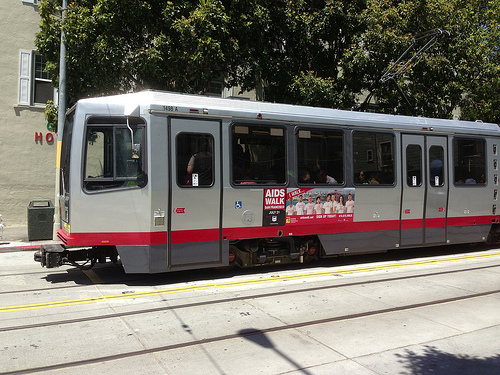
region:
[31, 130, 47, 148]
red letter on building.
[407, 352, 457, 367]
shadow on the sidewalk.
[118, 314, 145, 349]
concrete between the tracks.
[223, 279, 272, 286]
yellow paint on concrete.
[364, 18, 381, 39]
leaves on the tree.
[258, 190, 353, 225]
poster on the train.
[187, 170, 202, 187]
sign on the door.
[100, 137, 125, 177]
window on the train.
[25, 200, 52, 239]
trash bin on sidewalk.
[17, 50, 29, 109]
shutter on the building.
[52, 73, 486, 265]
the train is silver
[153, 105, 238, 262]
train's door is closed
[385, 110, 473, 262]
train's door is closed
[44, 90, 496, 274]
Red, gray and white streetcar with a lot of windows and 3 doors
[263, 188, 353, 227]
sign for Aids Walk including 8 people in white t-shirts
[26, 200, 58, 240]
gray trashcan with bowed top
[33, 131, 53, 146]
H O in red with cement background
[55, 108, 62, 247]
yellow and gray pole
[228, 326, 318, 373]
streetlight shaow top part on street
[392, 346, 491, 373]
treetop shadow on street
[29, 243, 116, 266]
Street trolley connector post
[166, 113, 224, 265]
street trolley single door red, white and gray with a window and 2 stickers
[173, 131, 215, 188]
window with white sticker and partial outline of a person in a gray shirt with a bent elbow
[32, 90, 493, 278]
white, gray and red mass transit car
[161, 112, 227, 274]
white, gray and red door of a mass transit car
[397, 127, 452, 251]
white, gray and red double doors of a mass transit car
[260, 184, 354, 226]
advertising sign on a mass transit car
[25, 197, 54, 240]
trash receptacle at the side of a road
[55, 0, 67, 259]
gray metal light pole at the side of a road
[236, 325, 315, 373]
shadow of a parking meter on the pavement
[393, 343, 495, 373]
shadow of a tree on the gray pavement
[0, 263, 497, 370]
shadow of two power lines on the gray pavement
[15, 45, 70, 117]
window on a building partially covered by a tree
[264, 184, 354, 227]
ad on side of trolly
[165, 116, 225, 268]
side door on trolly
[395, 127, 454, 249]
double door on trolly side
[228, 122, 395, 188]
window on side of trolly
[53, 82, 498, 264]
silver and red trolly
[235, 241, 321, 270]
train wheels and suspension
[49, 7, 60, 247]
light pole behind trolly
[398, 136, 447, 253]
side doors with windows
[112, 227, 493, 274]
dark gray boarder on bottom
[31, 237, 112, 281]
train car connector